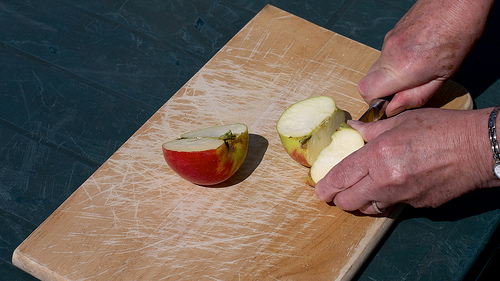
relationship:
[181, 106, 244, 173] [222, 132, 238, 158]
apple has stem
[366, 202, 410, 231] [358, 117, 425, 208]
ring on hand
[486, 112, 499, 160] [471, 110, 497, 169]
watch on wrist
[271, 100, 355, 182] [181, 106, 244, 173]
half of apple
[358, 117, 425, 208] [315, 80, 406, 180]
hand ia cutting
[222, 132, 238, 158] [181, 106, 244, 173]
stem of apple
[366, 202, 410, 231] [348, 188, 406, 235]
ring on finger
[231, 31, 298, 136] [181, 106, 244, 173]
board with apple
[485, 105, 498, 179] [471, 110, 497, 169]
watch on wrist